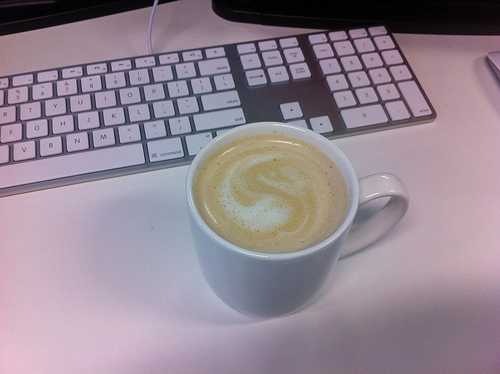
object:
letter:
[45, 139, 55, 150]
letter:
[57, 119, 67, 129]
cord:
[145, 0, 159, 55]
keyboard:
[0, 24, 436, 199]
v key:
[10, 139, 35, 163]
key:
[331, 88, 359, 109]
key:
[5, 84, 31, 105]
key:
[29, 80, 55, 102]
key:
[55, 77, 78, 96]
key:
[127, 67, 151, 88]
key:
[150, 66, 173, 83]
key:
[173, 62, 198, 81]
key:
[242, 67, 267, 86]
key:
[288, 61, 311, 81]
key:
[345, 71, 372, 90]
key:
[79, 73, 104, 94]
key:
[104, 71, 127, 90]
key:
[194, 57, 231, 78]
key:
[198, 89, 243, 112]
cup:
[183, 119, 410, 320]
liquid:
[194, 129, 350, 253]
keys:
[0, 141, 146, 192]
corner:
[482, 51, 487, 66]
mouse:
[483, 52, 499, 77]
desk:
[0, 0, 499, 373]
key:
[6, 71, 36, 88]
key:
[34, 69, 60, 83]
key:
[61, 65, 82, 80]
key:
[86, 59, 109, 76]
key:
[110, 57, 134, 73]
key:
[155, 53, 180, 65]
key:
[181, 49, 206, 65]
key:
[202, 45, 227, 59]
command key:
[143, 135, 186, 166]